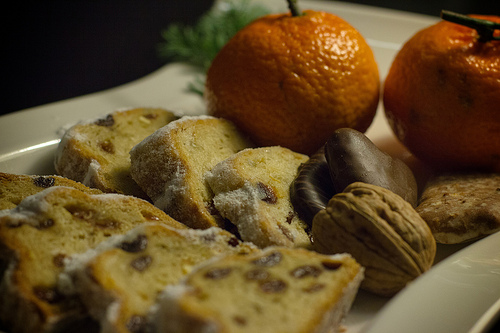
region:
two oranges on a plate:
[184, 11, 499, 176]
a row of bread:
[36, 88, 331, 256]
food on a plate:
[0, 1, 495, 330]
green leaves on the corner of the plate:
[164, 8, 264, 96]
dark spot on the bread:
[112, 231, 151, 256]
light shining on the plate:
[2, 138, 67, 165]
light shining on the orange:
[306, 26, 356, 74]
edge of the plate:
[468, 302, 497, 332]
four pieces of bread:
[1, 164, 372, 331]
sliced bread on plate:
[23, 106, 380, 311]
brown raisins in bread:
[34, 187, 344, 301]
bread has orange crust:
[185, 231, 355, 311]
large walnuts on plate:
[324, 186, 427, 286]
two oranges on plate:
[195, 26, 495, 151]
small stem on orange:
[270, 2, 295, 22]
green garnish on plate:
[155, 1, 280, 73]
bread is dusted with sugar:
[119, 122, 195, 204]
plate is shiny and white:
[49, 76, 455, 331]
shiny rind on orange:
[383, 31, 487, 151]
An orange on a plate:
[199, 1, 384, 152]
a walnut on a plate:
[309, 179, 440, 290]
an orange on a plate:
[378, 11, 498, 171]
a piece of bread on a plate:
[55, 97, 208, 202]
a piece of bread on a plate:
[127, 104, 270, 231]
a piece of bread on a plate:
[213, 142, 343, 248]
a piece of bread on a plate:
[150, 237, 370, 332]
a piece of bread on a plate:
[64, 222, 251, 332]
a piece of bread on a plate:
[10, 185, 204, 329]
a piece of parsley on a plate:
[151, 4, 293, 89]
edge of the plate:
[461, 300, 498, 331]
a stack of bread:
[44, 96, 362, 257]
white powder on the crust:
[201, 150, 252, 224]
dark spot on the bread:
[118, 233, 153, 255]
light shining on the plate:
[3, 130, 60, 160]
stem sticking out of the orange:
[284, 0, 306, 21]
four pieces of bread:
[0, 164, 386, 329]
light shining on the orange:
[318, 25, 363, 65]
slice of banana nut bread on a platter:
[151, 238, 363, 331]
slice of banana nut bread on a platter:
[73, 224, 268, 331]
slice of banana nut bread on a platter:
[3, 184, 190, 331]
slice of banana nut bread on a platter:
[2, 169, 102, 264]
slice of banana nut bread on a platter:
[204, 144, 323, 250]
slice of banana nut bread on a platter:
[128, 113, 260, 241]